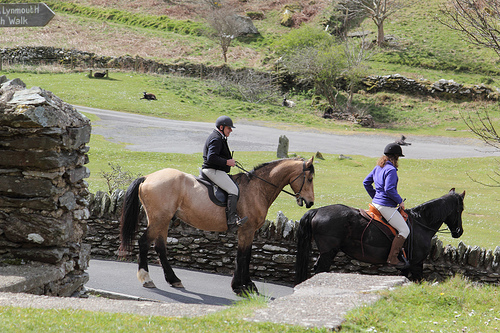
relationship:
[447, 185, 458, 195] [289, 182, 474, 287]
ear of horse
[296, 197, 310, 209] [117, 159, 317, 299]
horse's mouth of horse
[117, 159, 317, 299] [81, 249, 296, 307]
horse standing on pavement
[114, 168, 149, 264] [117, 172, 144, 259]
tail on tail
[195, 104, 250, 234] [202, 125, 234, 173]
man wearing jacket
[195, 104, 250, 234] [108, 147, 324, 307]
man on horse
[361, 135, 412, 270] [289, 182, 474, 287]
person on horse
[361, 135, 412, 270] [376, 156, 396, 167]
person with hair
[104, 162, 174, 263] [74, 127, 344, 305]
tail of horse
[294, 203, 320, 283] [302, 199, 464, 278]
tail of horse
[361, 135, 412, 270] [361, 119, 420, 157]
person wearing hat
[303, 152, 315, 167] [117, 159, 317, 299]
ear of horse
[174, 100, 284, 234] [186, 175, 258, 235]
man in boots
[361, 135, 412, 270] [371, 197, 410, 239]
person wearing pants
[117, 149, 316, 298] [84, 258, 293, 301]
horse trotting on pavement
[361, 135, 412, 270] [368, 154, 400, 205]
person wearing shirt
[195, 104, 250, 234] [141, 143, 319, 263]
man riding horse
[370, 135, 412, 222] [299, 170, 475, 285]
person riding horse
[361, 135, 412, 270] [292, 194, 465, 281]
person riding horse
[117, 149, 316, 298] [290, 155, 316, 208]
horse has head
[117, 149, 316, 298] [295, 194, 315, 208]
horse has mouth